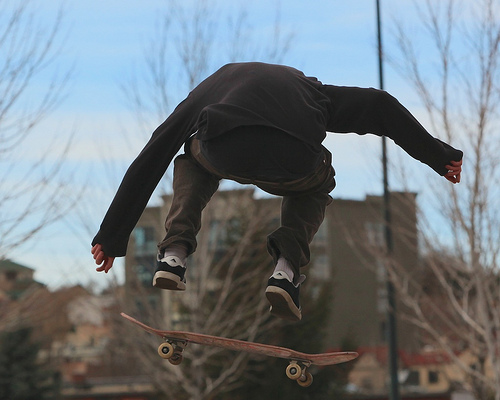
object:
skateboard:
[113, 303, 363, 390]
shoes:
[255, 265, 315, 328]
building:
[114, 183, 432, 377]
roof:
[0, 251, 40, 274]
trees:
[0, 0, 102, 272]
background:
[0, 158, 500, 400]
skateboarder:
[88, 54, 471, 323]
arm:
[327, 80, 468, 186]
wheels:
[153, 339, 178, 362]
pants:
[149, 142, 343, 270]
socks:
[267, 241, 299, 284]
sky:
[289, 3, 370, 53]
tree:
[354, 0, 500, 400]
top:
[175, 54, 343, 150]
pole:
[372, 0, 405, 400]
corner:
[0, 0, 55, 400]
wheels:
[282, 360, 305, 382]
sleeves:
[92, 73, 221, 248]